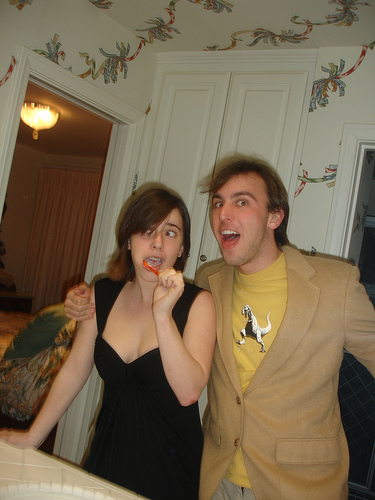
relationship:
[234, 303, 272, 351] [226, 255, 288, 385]
dinosaur across shirt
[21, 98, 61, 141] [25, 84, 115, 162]
light across ceiling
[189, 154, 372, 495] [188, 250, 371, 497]
man wearing suit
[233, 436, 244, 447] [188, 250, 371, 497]
button of a suit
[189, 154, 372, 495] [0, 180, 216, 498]
man standing next to woman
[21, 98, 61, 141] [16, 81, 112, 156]
light attached to ceiling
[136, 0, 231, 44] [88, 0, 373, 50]
graphics on ceiling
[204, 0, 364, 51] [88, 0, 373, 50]
graphics on ceiling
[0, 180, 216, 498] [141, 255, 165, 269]
woman has mouth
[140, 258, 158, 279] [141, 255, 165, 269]
toothbrush in mouth